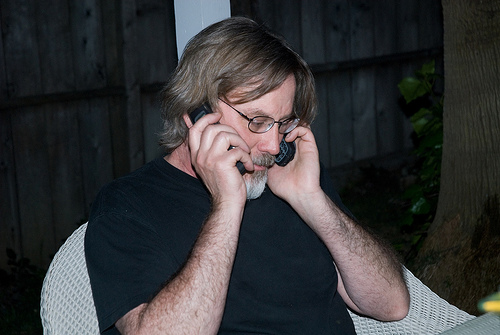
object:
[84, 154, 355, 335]
shirt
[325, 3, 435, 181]
board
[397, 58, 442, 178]
leaves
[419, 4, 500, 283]
tree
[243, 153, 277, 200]
beard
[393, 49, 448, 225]
plants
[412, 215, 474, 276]
ground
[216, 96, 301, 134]
eyeglasses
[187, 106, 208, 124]
cell phone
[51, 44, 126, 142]
fence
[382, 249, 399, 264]
hair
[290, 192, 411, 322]
arm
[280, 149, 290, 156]
buttons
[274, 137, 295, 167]
cell phone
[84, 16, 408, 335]
man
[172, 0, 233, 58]
post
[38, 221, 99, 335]
chair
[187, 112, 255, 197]
hand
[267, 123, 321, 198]
hand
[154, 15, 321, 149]
hair